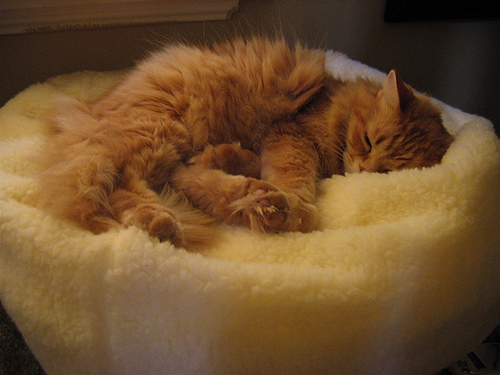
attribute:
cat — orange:
[71, 40, 440, 233]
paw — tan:
[124, 199, 191, 256]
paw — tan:
[228, 170, 333, 240]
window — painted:
[7, 1, 242, 34]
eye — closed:
[362, 129, 372, 151]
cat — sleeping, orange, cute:
[47, 30, 462, 245]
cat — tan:
[0, 11, 456, 251]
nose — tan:
[356, 163, 376, 173]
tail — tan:
[48, 95, 104, 217]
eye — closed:
[375, 159, 405, 173]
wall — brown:
[5, 9, 498, 143]